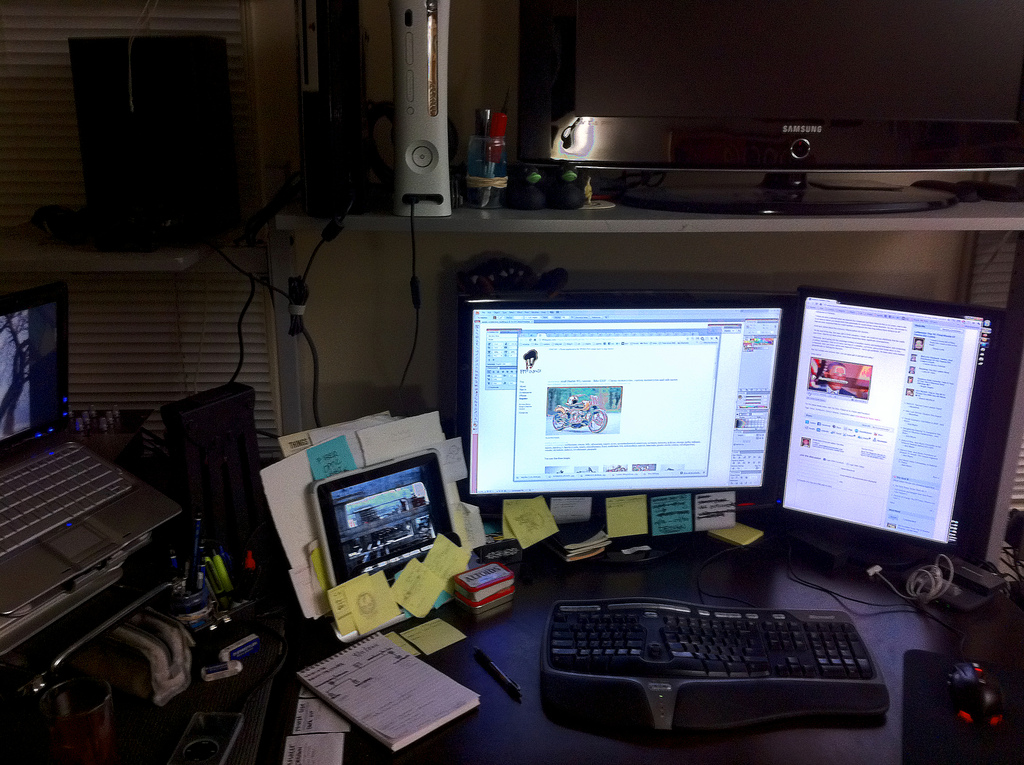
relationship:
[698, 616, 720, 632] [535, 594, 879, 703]
key on keyboard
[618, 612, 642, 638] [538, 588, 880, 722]
key on keyboard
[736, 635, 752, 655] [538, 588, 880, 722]
key on keyboard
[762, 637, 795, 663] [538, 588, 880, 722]
key on keyboard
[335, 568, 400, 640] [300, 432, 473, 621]
post-it on monitor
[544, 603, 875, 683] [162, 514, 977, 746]
keyboard on table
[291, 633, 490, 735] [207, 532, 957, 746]
notepad on table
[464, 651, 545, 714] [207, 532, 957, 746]
pen on table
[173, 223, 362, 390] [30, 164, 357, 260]
cords hanging from shelf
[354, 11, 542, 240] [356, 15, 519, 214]
speaker on shelf